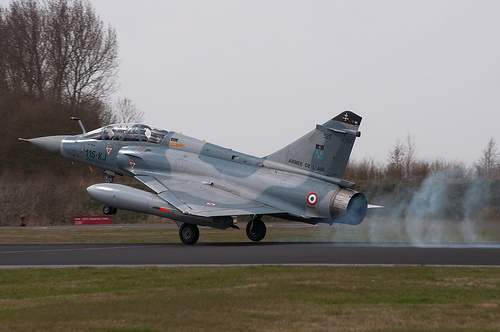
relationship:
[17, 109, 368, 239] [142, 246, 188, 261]
jet on runway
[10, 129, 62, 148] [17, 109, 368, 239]
nose of jet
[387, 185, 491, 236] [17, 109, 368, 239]
exhaust from jet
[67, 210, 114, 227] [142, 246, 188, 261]
structure on runway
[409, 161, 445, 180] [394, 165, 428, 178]
trees in background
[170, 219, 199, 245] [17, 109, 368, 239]
wheels on jet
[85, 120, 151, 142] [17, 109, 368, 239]
cockpit in jet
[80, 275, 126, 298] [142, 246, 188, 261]
grass around runway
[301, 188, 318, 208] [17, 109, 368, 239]
marks on jet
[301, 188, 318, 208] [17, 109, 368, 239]
target on jet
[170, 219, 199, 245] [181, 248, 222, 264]
wheel to pavemet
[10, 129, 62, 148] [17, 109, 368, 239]
nose on jet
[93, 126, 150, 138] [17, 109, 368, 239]
window of jet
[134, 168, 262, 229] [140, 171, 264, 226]
wing shaped like trangle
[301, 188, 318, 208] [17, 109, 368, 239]
bullseye of jet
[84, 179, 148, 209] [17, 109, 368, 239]
missile of jet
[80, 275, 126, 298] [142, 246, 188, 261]
grass surrounding runway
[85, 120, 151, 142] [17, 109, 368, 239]
cockpit of jet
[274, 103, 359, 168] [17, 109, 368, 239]
tail of jet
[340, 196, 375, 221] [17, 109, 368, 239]
afterburner of jet